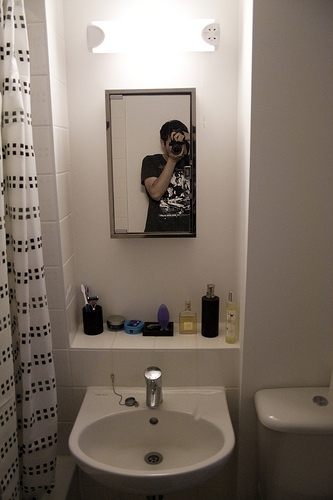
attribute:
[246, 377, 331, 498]
toilet — white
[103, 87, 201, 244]
frame — silver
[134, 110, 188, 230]
reflection — man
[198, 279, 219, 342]
perfume bottle — tall, black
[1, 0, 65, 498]
shower curtain — black, white, geometric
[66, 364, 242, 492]
sink — white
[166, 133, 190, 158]
camera — black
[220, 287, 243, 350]
toiletry — flowered, yellow, tall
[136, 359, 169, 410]
faucet — silver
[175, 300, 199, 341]
bottle — perfume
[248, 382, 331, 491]
tank — white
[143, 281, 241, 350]
products — hygiene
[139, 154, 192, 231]
shirt — white, black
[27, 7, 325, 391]
wall — white